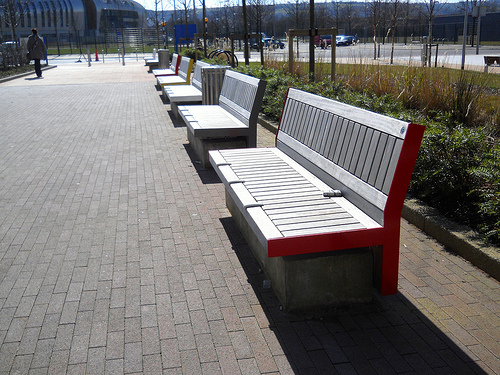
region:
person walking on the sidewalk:
[20, 24, 52, 81]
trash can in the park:
[185, 60, 240, 98]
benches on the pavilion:
[151, 65, 433, 342]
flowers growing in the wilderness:
[425, 59, 499, 109]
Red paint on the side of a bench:
[261, 118, 433, 303]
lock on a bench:
[323, 174, 342, 206]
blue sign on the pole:
[166, 18, 202, 44]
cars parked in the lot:
[308, 29, 364, 45]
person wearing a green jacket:
[24, 30, 46, 54]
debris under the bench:
[245, 261, 276, 304]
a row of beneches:
[204, 61, 493, 353]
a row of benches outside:
[125, 54, 399, 339]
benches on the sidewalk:
[112, 45, 482, 374]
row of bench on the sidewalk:
[160, 17, 499, 363]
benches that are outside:
[119, 29, 478, 370]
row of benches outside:
[152, 39, 496, 339]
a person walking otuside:
[32, 27, 87, 112]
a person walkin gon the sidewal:
[46, 31, 154, 141]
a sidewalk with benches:
[133, 20, 418, 359]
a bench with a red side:
[257, 92, 457, 299]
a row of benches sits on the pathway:
[146, 43, 421, 308]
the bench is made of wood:
[199, 85, 421, 297]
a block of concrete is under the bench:
[218, 179, 372, 313]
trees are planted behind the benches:
[158, 5, 486, 125]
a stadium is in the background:
[4, 3, 188, 58]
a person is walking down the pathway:
[21, 28, 53, 81]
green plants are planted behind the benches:
[231, 58, 496, 258]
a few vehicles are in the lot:
[239, 27, 357, 56]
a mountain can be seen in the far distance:
[151, 1, 449, 36]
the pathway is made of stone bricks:
[18, 137, 243, 373]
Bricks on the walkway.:
[79, 262, 175, 373]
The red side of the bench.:
[386, 104, 426, 311]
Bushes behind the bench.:
[424, 115, 493, 221]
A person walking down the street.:
[19, 18, 67, 93]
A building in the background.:
[21, 0, 168, 58]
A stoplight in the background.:
[200, 12, 216, 34]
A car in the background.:
[244, 20, 299, 60]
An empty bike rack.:
[199, 38, 248, 78]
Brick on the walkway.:
[74, 91, 129, 156]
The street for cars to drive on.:
[367, 36, 465, 65]